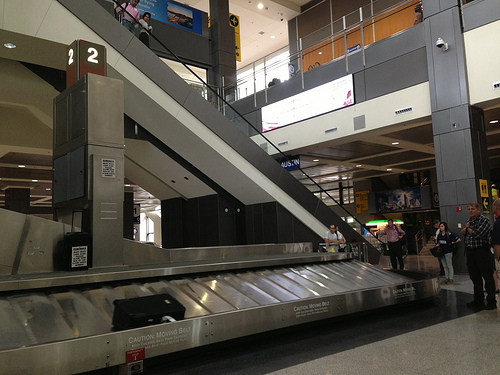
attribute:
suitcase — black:
[110, 292, 189, 330]